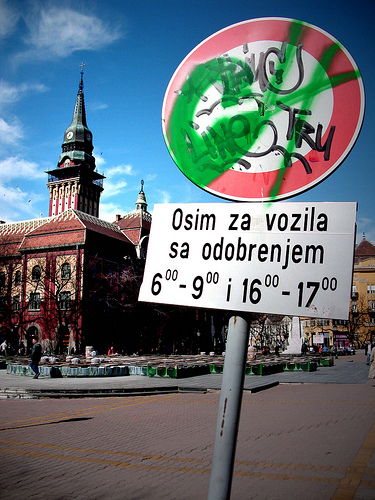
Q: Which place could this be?
A: It is a church.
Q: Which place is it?
A: It is a church.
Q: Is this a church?
A: Yes, it is a church.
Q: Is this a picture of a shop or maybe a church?
A: It is showing a church.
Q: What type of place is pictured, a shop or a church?
A: It is a church.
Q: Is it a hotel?
A: No, it is a church.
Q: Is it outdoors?
A: Yes, it is outdoors.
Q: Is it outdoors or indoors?
A: It is outdoors.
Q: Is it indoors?
A: No, it is outdoors.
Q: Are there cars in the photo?
A: No, there are no cars.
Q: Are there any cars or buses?
A: No, there are no cars or buses.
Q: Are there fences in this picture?
A: No, there are no fences.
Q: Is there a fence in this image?
A: No, there are no fences.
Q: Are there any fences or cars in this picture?
A: No, there are no fences or cars.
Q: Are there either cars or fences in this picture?
A: No, there are no fences or cars.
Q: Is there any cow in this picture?
A: Yes, there is a cow.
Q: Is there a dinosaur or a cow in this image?
A: Yes, there is a cow.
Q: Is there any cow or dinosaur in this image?
A: Yes, there is a cow.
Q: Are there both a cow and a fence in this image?
A: No, there is a cow but no fences.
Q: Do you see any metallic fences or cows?
A: Yes, there is a metal cow.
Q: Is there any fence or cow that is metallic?
A: Yes, the cow is metallic.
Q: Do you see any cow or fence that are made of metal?
A: Yes, the cow is made of metal.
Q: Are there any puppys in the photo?
A: No, there are no puppys.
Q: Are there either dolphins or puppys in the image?
A: No, there are no puppys or dolphins.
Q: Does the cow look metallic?
A: Yes, the cow is metallic.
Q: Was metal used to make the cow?
A: Yes, the cow is made of metal.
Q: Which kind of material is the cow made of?
A: The cow is made of metal.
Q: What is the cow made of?
A: The cow is made of metal.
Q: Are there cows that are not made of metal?
A: No, there is a cow but it is made of metal.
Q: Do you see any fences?
A: No, there are no fences.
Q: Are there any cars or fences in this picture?
A: No, there are no fences or cars.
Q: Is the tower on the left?
A: Yes, the tower is on the left of the image.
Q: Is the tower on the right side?
A: No, the tower is on the left of the image.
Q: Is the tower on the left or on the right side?
A: The tower is on the left of the image.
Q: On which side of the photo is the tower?
A: The tower is on the left of the image.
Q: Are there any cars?
A: No, there are no cars.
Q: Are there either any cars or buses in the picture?
A: No, there are no cars or buses.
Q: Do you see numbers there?
A: Yes, there are numbers.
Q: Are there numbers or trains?
A: Yes, there are numbers.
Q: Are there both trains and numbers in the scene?
A: No, there are numbers but no trains.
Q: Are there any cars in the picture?
A: No, there are no cars.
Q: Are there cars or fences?
A: No, there are no cars or fences.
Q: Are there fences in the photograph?
A: No, there are no fences.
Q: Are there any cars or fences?
A: No, there are no fences or cars.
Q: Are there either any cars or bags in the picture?
A: No, there are no cars or bags.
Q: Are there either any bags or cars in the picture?
A: No, there are no cars or bags.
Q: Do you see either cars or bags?
A: No, there are no cars or bags.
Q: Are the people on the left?
A: Yes, the people are on the left of the image.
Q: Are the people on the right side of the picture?
A: No, the people are on the left of the image.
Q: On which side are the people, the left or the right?
A: The people are on the left of the image.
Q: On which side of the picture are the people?
A: The people are on the left of the image.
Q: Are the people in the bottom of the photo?
A: Yes, the people are in the bottom of the image.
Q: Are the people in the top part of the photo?
A: No, the people are in the bottom of the image.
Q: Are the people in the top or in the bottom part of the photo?
A: The people are in the bottom of the image.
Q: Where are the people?
A: The people are on the sidewalk.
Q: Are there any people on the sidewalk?
A: Yes, there are people on the sidewalk.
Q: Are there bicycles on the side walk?
A: No, there are people on the side walk.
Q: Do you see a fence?
A: No, there are no fences.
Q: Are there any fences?
A: No, there are no fences.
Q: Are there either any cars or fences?
A: No, there are no fences or cars.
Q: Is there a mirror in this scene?
A: No, there are no mirrors.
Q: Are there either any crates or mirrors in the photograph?
A: No, there are no mirrors or crates.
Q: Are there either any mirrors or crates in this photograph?
A: No, there are no mirrors or crates.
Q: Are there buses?
A: No, there are no buses.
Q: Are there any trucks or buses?
A: No, there are no buses or trucks.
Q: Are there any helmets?
A: Yes, there is a helmet.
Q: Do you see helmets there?
A: Yes, there is a helmet.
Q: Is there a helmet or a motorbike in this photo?
A: Yes, there is a helmet.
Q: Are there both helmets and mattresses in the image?
A: No, there is a helmet but no mattresses.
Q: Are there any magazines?
A: No, there are no magazines.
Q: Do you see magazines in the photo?
A: No, there are no magazines.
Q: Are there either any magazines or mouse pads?
A: No, there are no magazines or mouse pads.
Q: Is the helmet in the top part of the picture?
A: Yes, the helmet is in the top of the image.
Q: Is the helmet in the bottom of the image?
A: No, the helmet is in the top of the image.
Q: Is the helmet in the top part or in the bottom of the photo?
A: The helmet is in the top of the image.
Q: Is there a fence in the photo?
A: No, there are no fences.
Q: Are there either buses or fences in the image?
A: No, there are no fences or buses.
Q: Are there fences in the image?
A: No, there are no fences.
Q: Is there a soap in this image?
A: No, there are no soaps.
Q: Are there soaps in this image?
A: No, there are no soaps.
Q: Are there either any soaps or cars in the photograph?
A: No, there are no soaps or cars.